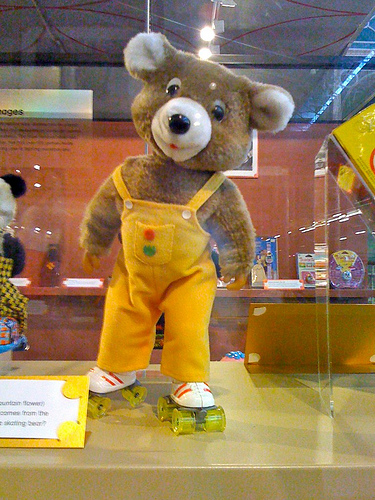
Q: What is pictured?
A: Stuffed toy.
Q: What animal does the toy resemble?
A: Bear.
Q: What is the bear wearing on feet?
A: Skates.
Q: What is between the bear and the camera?
A: Glass.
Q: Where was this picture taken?
A: A museum.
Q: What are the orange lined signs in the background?
A: Display description.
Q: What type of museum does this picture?
A: Toy museum.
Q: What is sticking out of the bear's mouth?
A: A tongue.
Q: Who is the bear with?
A: No one.